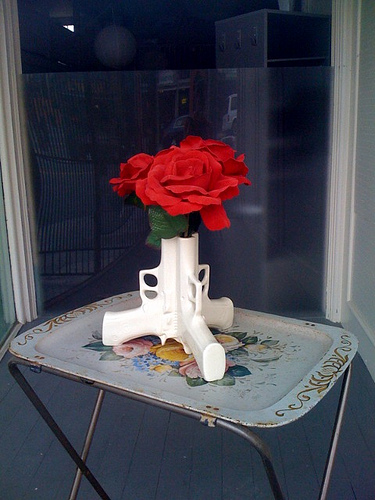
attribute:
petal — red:
[200, 202, 234, 232]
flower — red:
[114, 133, 252, 236]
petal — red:
[181, 193, 223, 207]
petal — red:
[134, 176, 160, 207]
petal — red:
[216, 159, 249, 180]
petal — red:
[125, 154, 152, 179]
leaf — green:
[146, 204, 189, 238]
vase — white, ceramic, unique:
[100, 232, 239, 383]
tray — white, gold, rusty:
[9, 290, 361, 432]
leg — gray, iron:
[321, 362, 354, 499]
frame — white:
[323, 0, 367, 321]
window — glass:
[18, 2, 332, 318]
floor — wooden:
[0, 316, 375, 498]